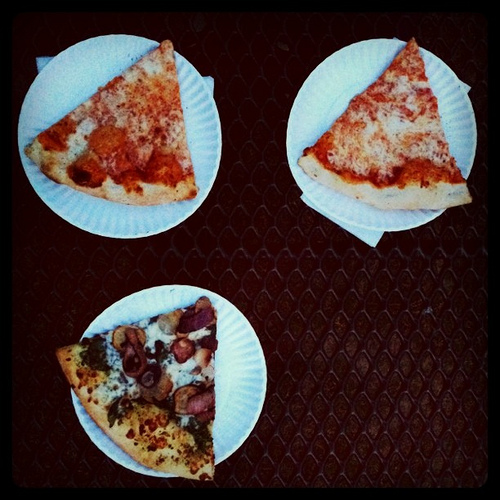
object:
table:
[10, 12, 485, 490]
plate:
[15, 35, 223, 243]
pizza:
[23, 36, 197, 207]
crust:
[119, 182, 193, 206]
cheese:
[114, 109, 147, 134]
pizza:
[53, 296, 231, 481]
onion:
[179, 307, 214, 332]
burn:
[71, 159, 107, 184]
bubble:
[50, 168, 67, 181]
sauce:
[149, 149, 164, 169]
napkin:
[203, 76, 214, 96]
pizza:
[296, 36, 472, 209]